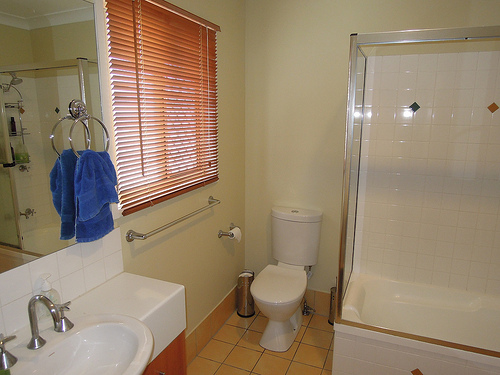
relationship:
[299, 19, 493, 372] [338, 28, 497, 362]
shower with door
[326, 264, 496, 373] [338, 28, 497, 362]
bathtub with door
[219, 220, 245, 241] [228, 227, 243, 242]
dispenser with toilet paper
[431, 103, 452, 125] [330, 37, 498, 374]
white tile in shower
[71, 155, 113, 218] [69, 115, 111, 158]
towel in towel ring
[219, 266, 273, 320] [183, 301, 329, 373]
container on floor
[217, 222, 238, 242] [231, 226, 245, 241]
holder for toilet paper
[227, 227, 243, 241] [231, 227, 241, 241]
roll of toilet paper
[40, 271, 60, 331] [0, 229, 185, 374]
dispenser on counter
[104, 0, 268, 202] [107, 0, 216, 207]
blinds hang from window